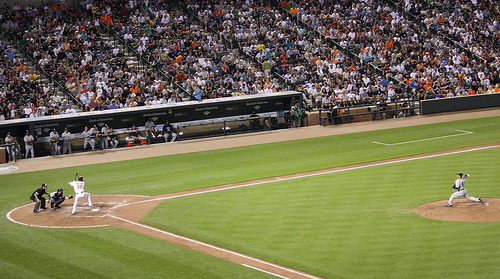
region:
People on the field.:
[12, 160, 234, 249]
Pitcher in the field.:
[313, 167, 491, 231]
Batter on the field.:
[47, 156, 117, 210]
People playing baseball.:
[26, 157, 138, 237]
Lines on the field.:
[157, 189, 254, 205]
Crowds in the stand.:
[97, 20, 344, 182]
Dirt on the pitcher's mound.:
[9, 168, 261, 254]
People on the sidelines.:
[65, 101, 357, 174]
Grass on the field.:
[131, 165, 319, 212]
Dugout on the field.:
[122, 86, 343, 166]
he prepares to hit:
[68, 171, 96, 217]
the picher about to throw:
[444, 168, 482, 215]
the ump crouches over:
[28, 179, 50, 214]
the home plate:
[89, 205, 100, 215]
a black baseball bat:
[72, 169, 81, 182]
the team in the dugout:
[4, 115, 174, 156]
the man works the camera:
[282, 100, 303, 130]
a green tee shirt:
[292, 107, 302, 120]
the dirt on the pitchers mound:
[412, 192, 494, 221]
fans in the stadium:
[5, 10, 494, 70]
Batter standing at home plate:
[56, 164, 106, 216]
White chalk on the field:
[106, 202, 293, 248]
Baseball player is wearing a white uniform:
[57, 167, 114, 226]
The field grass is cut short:
[243, 200, 401, 260]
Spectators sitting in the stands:
[54, 36, 269, 88]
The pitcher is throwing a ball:
[418, 155, 497, 218]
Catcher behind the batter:
[47, 178, 74, 218]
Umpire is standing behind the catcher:
[23, 175, 56, 212]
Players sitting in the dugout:
[7, 109, 198, 153]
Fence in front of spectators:
[315, 94, 432, 130]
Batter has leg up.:
[57, 168, 107, 223]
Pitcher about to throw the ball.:
[440, 161, 483, 209]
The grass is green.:
[291, 197, 386, 258]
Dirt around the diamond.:
[110, 160, 499, 276]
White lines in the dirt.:
[106, 201, 186, 242]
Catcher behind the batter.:
[44, 180, 74, 217]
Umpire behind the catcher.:
[25, 173, 50, 214]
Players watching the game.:
[2, 115, 182, 159]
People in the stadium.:
[6, 0, 479, 92]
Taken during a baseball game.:
[5, 2, 499, 266]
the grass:
[261, 188, 276, 240]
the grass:
[310, 174, 340, 256]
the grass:
[290, 182, 322, 264]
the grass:
[317, 130, 354, 271]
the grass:
[268, 171, 332, 273]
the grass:
[292, 158, 339, 268]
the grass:
[295, 127, 313, 181]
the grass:
[315, 132, 330, 273]